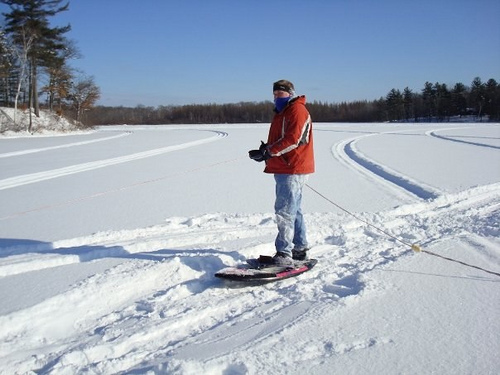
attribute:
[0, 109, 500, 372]
snow — white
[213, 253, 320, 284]
board — large, covered, pink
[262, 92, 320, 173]
coat — black, orange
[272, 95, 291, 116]
mask — blue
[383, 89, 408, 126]
tree — tall, evergreen, green, far off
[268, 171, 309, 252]
pants — blue, denim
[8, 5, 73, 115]
tree — large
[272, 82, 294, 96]
sweatband — black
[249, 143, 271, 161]
gloves — black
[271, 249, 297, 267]
shoe — black